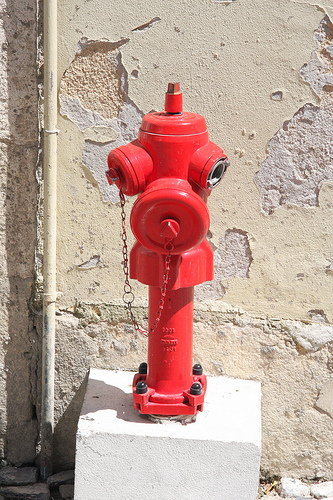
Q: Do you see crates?
A: No, there are no crates.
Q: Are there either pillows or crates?
A: No, there are no crates or pillows.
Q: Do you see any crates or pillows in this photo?
A: No, there are no crates or pillows.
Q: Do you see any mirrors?
A: No, there are no mirrors.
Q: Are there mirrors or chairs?
A: No, there are no mirrors or chairs.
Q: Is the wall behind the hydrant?
A: Yes, the wall is behind the hydrant.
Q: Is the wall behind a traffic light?
A: No, the wall is behind the hydrant.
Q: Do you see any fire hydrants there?
A: Yes, there is a fire hydrant.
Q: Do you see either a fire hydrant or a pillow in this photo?
A: Yes, there is a fire hydrant.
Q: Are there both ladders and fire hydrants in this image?
A: No, there is a fire hydrant but no ladders.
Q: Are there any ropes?
A: No, there are no ropes.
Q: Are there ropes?
A: No, there are no ropes.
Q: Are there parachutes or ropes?
A: No, there are no ropes or parachutes.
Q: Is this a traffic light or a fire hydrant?
A: This is a fire hydrant.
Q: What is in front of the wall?
A: The fire hydrant is in front of the wall.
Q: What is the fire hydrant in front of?
A: The fire hydrant is in front of the wall.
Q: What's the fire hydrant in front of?
A: The fire hydrant is in front of the wall.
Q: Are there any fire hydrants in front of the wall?
A: Yes, there is a fire hydrant in front of the wall.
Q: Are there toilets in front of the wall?
A: No, there is a fire hydrant in front of the wall.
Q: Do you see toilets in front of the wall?
A: No, there is a fire hydrant in front of the wall.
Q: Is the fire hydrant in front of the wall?
A: Yes, the fire hydrant is in front of the wall.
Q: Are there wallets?
A: No, there are no wallets.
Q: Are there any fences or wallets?
A: No, there are no wallets or fences.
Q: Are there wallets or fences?
A: No, there are no wallets or fences.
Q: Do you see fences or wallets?
A: No, there are no wallets or fences.